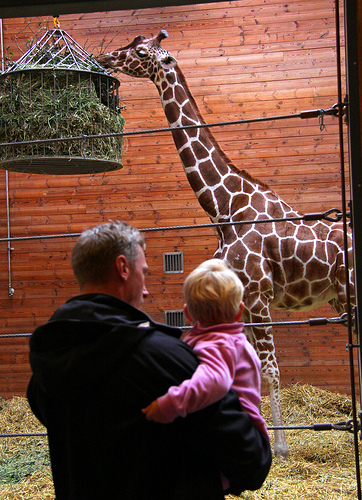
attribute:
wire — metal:
[255, 307, 359, 345]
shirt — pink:
[156, 318, 277, 439]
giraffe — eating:
[95, 32, 360, 463]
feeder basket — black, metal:
[2, 18, 126, 180]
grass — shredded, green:
[2, 74, 125, 158]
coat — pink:
[159, 323, 270, 488]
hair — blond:
[176, 254, 247, 322]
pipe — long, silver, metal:
[4, 168, 14, 296]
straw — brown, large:
[55, 98, 122, 132]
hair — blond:
[186, 259, 244, 318]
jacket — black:
[25, 291, 271, 498]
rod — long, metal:
[330, 99, 361, 493]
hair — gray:
[73, 220, 145, 291]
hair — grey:
[70, 216, 136, 283]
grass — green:
[15, 69, 110, 137]